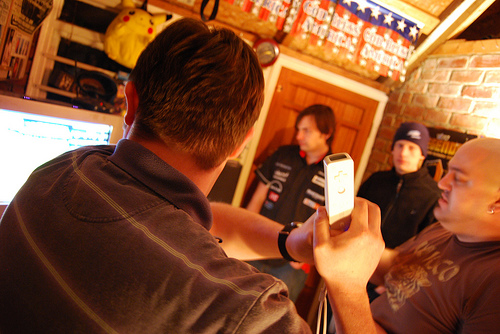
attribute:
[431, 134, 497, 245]
man — in background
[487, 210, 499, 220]
earring — silver, hoop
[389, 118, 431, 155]
beanie — dark colored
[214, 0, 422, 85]
banner — red white and blue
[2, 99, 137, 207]
tv screen — in background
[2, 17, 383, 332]
man — in foreground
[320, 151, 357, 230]
remote — white, square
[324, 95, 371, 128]
door — brown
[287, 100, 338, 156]
hair — brown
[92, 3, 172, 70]
stuffed animal — yellow, smiling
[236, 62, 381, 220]
door — wooden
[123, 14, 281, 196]
head — back view, person's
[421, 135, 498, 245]
man's head — side view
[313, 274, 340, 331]
cord — white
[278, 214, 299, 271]
watch — black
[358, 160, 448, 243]
jacket — black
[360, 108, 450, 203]
beanie — dark 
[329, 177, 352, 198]
button — circular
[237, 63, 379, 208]
door — wood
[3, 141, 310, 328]
shirt — striped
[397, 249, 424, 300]
design — golden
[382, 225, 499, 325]
shirt — dark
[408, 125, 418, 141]
design — white